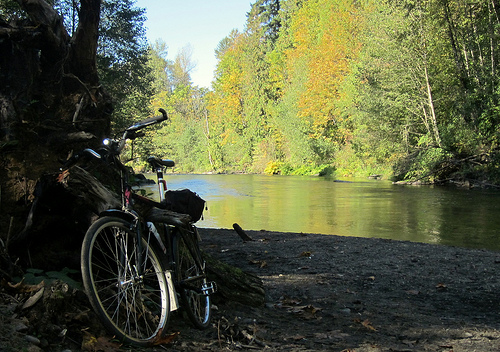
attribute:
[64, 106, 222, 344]
bike — parked, black, silver, grey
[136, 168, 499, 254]
lake — tree-lined, sunlit, water filled, calm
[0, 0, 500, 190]
trees — sunlit, yellow green, brown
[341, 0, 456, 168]
tree — green, reflected, brown, birch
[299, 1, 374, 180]
tree — green, reflected, yellow, leafy, orange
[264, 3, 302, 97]
tree — green, reflected, yellow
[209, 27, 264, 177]
tree — green, reflected, yellow, orange, leafy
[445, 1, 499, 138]
tree — green, brown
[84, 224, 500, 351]
bank — dirt, shaded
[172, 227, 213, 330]
tire — black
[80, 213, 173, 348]
tire — black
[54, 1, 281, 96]
sky — clear, blue, pale, light blue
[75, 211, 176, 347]
wheel — black, silver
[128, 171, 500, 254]
water — calm, shady, sunny, sunlit, reflective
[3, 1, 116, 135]
tree — old, brown, green, large, growing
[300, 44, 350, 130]
leaves — orange, green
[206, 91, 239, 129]
leaves — orange, green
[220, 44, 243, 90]
leaves — orange, green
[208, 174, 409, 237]
reflection — yellow, green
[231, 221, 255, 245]
tree stump — small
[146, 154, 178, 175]
seat — black, silver